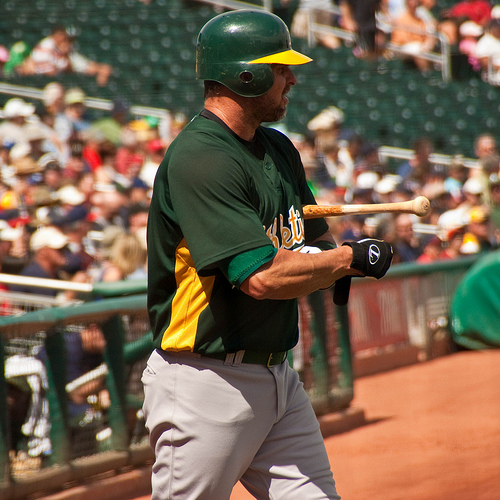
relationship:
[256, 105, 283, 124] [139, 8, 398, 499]
beard of man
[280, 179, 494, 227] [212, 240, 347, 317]
bat under arm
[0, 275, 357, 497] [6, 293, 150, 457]
fence with padding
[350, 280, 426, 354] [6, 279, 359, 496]
sign posted on fence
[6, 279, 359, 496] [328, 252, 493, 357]
fence posted on fence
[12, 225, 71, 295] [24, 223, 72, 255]
man wearing hat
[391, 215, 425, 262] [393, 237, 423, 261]
man wearing shirt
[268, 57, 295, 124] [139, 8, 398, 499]
face of man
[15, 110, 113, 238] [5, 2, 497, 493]
fans in stadium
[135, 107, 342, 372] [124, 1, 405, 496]
shirt on player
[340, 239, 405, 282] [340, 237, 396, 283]
glove on hand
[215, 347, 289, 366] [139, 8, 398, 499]
belt on man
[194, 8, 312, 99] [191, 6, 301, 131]
green/yellow helmet on man's head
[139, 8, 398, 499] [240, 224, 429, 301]
man has hand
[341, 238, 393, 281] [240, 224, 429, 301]
glove on hand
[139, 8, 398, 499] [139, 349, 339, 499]
man wearing pants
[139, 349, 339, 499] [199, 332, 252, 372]
pants have loops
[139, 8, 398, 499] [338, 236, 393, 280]
man has glove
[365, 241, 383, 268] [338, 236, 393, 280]
design on glove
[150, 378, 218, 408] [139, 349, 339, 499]
pocket on pants